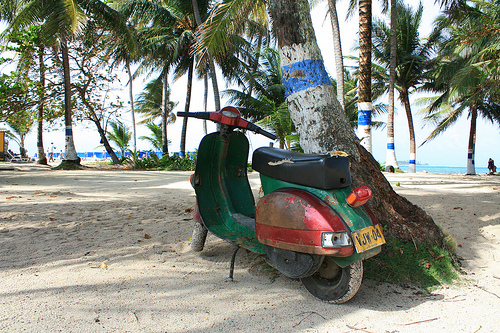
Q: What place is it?
A: It is a beach.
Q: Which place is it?
A: It is a beach.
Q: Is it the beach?
A: Yes, it is the beach.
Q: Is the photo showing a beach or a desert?
A: It is showing a beach.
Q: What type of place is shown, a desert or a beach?
A: It is a beach.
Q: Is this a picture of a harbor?
A: No, the picture is showing a beach.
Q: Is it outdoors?
A: Yes, it is outdoors.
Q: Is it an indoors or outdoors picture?
A: It is outdoors.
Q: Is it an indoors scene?
A: No, it is outdoors.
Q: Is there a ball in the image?
A: No, there are no balls.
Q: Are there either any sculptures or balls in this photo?
A: No, there are no balls or sculptures.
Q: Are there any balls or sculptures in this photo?
A: No, there are no balls or sculptures.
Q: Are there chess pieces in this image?
A: No, there are no chess pieces.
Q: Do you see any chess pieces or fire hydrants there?
A: No, there are no chess pieces or fire hydrants.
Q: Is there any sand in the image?
A: Yes, there is sand.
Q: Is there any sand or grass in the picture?
A: Yes, there is sand.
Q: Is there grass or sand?
A: Yes, there is sand.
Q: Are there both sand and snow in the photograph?
A: No, there is sand but no snow.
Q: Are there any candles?
A: No, there are no candles.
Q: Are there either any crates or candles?
A: No, there are no candles or crates.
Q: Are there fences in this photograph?
A: No, there are no fences.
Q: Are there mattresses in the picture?
A: No, there are no mattresses.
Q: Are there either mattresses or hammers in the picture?
A: No, there are no mattresses or hammers.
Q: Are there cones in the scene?
A: No, there are no cones.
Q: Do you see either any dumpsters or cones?
A: No, there are no cones or dumpsters.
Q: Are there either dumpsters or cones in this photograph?
A: No, there are no cones or dumpsters.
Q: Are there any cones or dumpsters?
A: No, there are no cones or dumpsters.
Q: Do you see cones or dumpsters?
A: No, there are no cones or dumpsters.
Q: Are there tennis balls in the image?
A: No, there are no tennis balls.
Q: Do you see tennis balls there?
A: No, there are no tennis balls.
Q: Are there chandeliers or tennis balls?
A: No, there are no tennis balls or chandeliers.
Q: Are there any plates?
A: Yes, there is a plate.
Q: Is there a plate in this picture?
A: Yes, there is a plate.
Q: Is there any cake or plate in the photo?
A: Yes, there is a plate.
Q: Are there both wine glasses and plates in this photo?
A: No, there is a plate but no wine glasses.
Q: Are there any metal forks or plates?
A: Yes, there is a metal plate.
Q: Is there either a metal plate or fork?
A: Yes, there is a metal plate.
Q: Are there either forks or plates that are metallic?
A: Yes, the plate is metallic.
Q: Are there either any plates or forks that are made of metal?
A: Yes, the plate is made of metal.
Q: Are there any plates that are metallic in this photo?
A: Yes, there is a metal plate.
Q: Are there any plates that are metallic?
A: Yes, there is a plate that is metallic.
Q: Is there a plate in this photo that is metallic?
A: Yes, there is a plate that is metallic.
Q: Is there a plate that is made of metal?
A: Yes, there is a plate that is made of metal.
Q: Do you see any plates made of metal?
A: Yes, there is a plate that is made of metal.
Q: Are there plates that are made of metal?
A: Yes, there is a plate that is made of metal.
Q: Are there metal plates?
A: Yes, there is a plate that is made of metal.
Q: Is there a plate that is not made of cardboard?
A: Yes, there is a plate that is made of metal.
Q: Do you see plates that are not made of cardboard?
A: Yes, there is a plate that is made of metal.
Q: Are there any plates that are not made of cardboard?
A: Yes, there is a plate that is made of metal.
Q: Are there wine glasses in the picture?
A: No, there are no wine glasses.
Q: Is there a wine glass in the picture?
A: No, there are no wine glasses.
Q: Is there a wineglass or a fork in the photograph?
A: No, there are no wine glasses or forks.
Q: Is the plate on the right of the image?
A: Yes, the plate is on the right of the image.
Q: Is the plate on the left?
A: No, the plate is on the right of the image.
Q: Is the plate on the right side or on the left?
A: The plate is on the right of the image.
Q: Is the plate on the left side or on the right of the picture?
A: The plate is on the right of the image.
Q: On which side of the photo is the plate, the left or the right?
A: The plate is on the right of the image.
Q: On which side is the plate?
A: The plate is on the right of the image.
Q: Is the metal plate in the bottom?
A: Yes, the plate is in the bottom of the image.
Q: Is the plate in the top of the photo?
A: No, the plate is in the bottom of the image.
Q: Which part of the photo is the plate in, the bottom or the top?
A: The plate is in the bottom of the image.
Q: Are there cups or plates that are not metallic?
A: No, there is a plate but it is metallic.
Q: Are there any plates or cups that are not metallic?
A: No, there is a plate but it is metallic.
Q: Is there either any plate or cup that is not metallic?
A: No, there is a plate but it is metallic.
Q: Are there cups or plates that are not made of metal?
A: No, there is a plate but it is made of metal.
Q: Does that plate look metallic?
A: Yes, the plate is metallic.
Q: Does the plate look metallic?
A: Yes, the plate is metallic.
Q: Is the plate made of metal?
A: Yes, the plate is made of metal.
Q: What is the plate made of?
A: The plate is made of metal.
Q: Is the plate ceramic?
A: No, the plate is metallic.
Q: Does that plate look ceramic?
A: No, the plate is metallic.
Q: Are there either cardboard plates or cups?
A: No, there is a plate but it is metallic.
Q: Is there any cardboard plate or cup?
A: No, there is a plate but it is metallic.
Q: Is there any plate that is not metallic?
A: No, there is a plate but it is metallic.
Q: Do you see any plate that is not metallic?
A: No, there is a plate but it is metallic.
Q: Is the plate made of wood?
A: No, the plate is made of metal.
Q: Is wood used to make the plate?
A: No, the plate is made of metal.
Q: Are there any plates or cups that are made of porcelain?
A: No, there is a plate but it is made of metal.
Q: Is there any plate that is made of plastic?
A: No, there is a plate but it is made of metal.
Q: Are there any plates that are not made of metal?
A: No, there is a plate but it is made of metal.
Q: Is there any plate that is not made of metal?
A: No, there is a plate but it is made of metal.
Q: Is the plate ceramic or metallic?
A: The plate is metallic.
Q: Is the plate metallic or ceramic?
A: The plate is metallic.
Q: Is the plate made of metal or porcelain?
A: The plate is made of metal.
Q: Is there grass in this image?
A: Yes, there is grass.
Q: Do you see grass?
A: Yes, there is grass.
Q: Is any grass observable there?
A: Yes, there is grass.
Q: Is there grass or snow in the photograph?
A: Yes, there is grass.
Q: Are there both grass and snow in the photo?
A: No, there is grass but no snow.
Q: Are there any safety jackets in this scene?
A: No, there are no safety jackets.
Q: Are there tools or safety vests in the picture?
A: No, there are no safety vests or tools.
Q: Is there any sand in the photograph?
A: Yes, there is sand.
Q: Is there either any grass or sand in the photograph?
A: Yes, there is sand.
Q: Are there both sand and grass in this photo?
A: Yes, there are both sand and grass.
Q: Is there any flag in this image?
A: No, there are no flags.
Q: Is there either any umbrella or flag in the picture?
A: No, there are no flags or umbrellas.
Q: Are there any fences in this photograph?
A: No, there are no fences.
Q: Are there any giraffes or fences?
A: No, there are no fences or giraffes.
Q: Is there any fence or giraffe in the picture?
A: No, there are no fences or giraffes.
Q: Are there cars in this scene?
A: No, there are no cars.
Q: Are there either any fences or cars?
A: No, there are no cars or fences.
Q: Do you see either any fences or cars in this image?
A: No, there are no cars or fences.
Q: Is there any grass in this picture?
A: Yes, there is grass.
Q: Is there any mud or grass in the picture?
A: Yes, there is grass.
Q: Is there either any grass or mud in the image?
A: Yes, there is grass.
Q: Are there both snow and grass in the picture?
A: No, there is grass but no snow.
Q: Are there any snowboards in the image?
A: No, there are no snowboards.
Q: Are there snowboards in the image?
A: No, there are no snowboards.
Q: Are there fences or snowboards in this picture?
A: No, there are no snowboards or fences.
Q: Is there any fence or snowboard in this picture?
A: No, there are no snowboards or fences.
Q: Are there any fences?
A: No, there are no fences.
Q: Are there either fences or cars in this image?
A: No, there are no fences or cars.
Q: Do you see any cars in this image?
A: No, there are no cars.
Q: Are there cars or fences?
A: No, there are no cars or fences.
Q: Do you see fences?
A: No, there are no fences.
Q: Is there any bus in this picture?
A: No, there are no buses.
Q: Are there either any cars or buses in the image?
A: No, there are no buses or cars.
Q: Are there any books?
A: No, there are no books.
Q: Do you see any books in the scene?
A: No, there are no books.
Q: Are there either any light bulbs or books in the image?
A: No, there are no books or light bulbs.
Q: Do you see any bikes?
A: Yes, there is a bike.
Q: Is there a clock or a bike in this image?
A: Yes, there is a bike.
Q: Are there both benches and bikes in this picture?
A: No, there is a bike but no benches.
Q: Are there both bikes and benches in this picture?
A: No, there is a bike but no benches.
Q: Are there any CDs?
A: No, there are no cds.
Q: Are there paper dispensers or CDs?
A: No, there are no CDs or paper dispensers.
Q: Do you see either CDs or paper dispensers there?
A: No, there are no CDs or paper dispensers.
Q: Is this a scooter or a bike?
A: This is a bike.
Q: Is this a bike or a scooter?
A: This is a bike.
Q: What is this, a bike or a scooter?
A: This is a bike.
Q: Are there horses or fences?
A: No, there are no fences or horses.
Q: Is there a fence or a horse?
A: No, there are no fences or horses.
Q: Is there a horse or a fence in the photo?
A: No, there are no fences or horses.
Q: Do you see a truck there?
A: No, there are no trucks.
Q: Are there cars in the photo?
A: No, there are no cars.